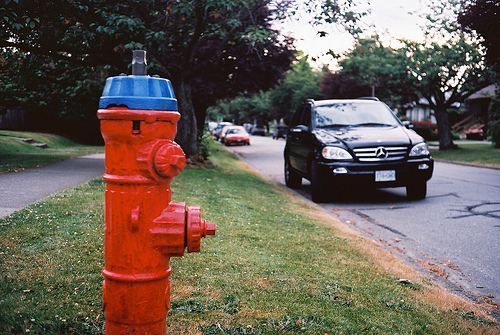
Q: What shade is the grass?
A: Green.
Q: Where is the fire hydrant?
A: In forefront.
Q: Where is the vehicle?
A: Along the street.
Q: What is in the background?
A: Trees.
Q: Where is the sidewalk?
A: Between grass.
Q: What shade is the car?
A: Black.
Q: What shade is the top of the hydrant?
A: Blue.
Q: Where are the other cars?
A: Background.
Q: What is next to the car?
A: Grass.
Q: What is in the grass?
A: Hydrant.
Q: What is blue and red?
A: Hydrant.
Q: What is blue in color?
A: Top of the hydrant.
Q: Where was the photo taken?
A: Outside somewhere.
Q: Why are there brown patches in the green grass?
A: Dried out.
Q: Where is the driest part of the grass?
A: Along street.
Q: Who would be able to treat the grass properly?
A: Landscaper.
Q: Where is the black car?
A: Parked next dead grass.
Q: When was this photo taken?
A: Daytime.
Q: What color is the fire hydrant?
A: Red.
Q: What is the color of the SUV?
A: Black.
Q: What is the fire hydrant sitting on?
A: Grass.